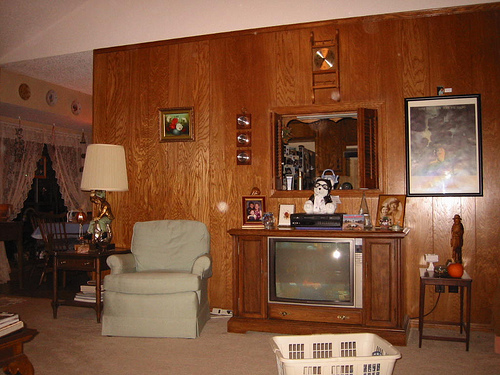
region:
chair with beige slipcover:
[92, 210, 217, 337]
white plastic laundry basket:
[269, 331, 396, 373]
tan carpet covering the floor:
[136, 340, 224, 370]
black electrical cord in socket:
[427, 295, 440, 313]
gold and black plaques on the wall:
[229, 100, 271, 174]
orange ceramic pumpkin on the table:
[441, 258, 468, 278]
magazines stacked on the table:
[0, 314, 29, 336]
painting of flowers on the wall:
[151, 97, 213, 146]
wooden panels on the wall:
[206, 51, 296, 91]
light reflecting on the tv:
[320, 238, 358, 258]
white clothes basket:
[264, 332, 411, 374]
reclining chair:
[102, 205, 209, 347]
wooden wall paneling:
[154, 146, 220, 203]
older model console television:
[224, 219, 411, 344]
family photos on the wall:
[400, 85, 494, 211]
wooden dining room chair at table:
[24, 205, 80, 261]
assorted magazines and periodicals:
[60, 269, 105, 307]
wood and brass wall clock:
[303, 30, 353, 108]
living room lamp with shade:
[76, 122, 131, 259]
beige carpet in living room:
[127, 339, 203, 369]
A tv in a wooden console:
[222, 218, 412, 345]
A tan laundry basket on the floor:
[264, 329, 401, 371]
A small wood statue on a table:
[445, 211, 467, 264]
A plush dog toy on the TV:
[300, 176, 340, 213]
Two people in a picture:
[238, 193, 265, 228]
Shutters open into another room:
[265, 105, 381, 192]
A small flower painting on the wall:
[152, 102, 199, 147]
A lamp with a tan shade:
[78, 138, 128, 255]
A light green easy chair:
[93, 212, 217, 339]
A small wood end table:
[48, 239, 134, 323]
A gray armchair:
[93, 207, 223, 344]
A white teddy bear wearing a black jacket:
[299, 170, 340, 219]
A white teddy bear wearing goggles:
[300, 175, 343, 215]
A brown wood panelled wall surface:
[153, 148, 215, 214]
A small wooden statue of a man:
[446, 210, 474, 264]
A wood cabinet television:
[223, 206, 425, 345]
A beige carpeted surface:
[77, 340, 213, 372]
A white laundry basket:
[259, 328, 413, 374]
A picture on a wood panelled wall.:
[391, 89, 493, 202]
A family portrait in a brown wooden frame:
[236, 188, 272, 233]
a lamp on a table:
[77, 141, 129, 259]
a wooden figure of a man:
[446, 211, 468, 274]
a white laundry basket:
[268, 328, 411, 373]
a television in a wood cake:
[218, 223, 415, 346]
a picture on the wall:
[401, 92, 487, 206]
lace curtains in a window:
[1, 112, 93, 301]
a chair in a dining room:
[32, 208, 72, 299]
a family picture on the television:
[240, 194, 268, 228]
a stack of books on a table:
[0, 308, 25, 342]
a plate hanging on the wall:
[41, 84, 58, 107]